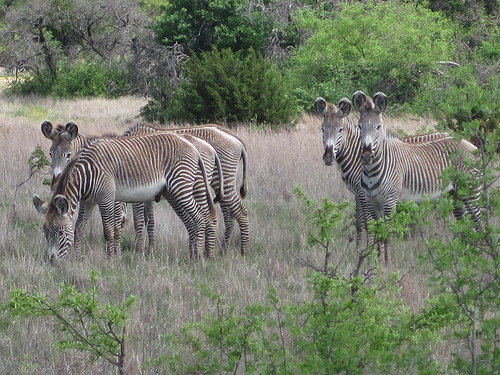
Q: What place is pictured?
A: It is a field.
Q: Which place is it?
A: It is a field.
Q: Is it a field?
A: Yes, it is a field.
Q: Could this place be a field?
A: Yes, it is a field.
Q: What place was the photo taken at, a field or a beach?
A: It was taken at a field.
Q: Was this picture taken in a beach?
A: No, the picture was taken in a field.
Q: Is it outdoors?
A: Yes, it is outdoors.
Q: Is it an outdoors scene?
A: Yes, it is outdoors.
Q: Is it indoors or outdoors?
A: It is outdoors.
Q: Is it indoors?
A: No, it is outdoors.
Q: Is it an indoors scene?
A: No, it is outdoors.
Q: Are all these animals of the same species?
A: Yes, all the animals are zebras.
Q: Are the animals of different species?
A: No, all the animals are zebras.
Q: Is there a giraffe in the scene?
A: No, there are no giraffes.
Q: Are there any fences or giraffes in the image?
A: No, there are no giraffes or fences.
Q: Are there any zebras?
A: Yes, there is a zebra.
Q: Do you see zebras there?
A: Yes, there is a zebra.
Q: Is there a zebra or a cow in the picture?
A: Yes, there is a zebra.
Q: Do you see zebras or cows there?
A: Yes, there is a zebra.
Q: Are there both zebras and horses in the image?
A: No, there is a zebra but no horses.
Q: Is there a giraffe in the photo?
A: No, there are no giraffes.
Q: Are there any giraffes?
A: No, there are no giraffes.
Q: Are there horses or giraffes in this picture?
A: No, there are no giraffes or horses.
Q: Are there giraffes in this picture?
A: No, there are no giraffes.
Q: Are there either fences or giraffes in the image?
A: No, there are no giraffes or fences.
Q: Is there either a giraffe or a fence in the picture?
A: No, there are no giraffes or fences.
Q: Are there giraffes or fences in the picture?
A: No, there are no giraffes or fences.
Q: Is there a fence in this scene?
A: No, there are no fences.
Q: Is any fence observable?
A: No, there are no fences.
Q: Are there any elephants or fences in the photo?
A: No, there are no fences or elephants.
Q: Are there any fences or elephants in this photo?
A: No, there are no fences or elephants.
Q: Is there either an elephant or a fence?
A: No, there are no fences or elephants.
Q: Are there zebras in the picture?
A: Yes, there is a zebra.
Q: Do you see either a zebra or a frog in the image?
A: Yes, there is a zebra.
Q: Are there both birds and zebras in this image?
A: No, there is a zebra but no birds.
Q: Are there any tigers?
A: No, there are no tigers.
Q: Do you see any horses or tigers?
A: No, there are no tigers or horses.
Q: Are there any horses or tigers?
A: No, there are no tigers or horses.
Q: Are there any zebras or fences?
A: Yes, there is a zebra.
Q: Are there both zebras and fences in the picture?
A: No, there is a zebra but no fences.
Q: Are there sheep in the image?
A: No, there are no sheep.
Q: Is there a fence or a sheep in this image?
A: No, there are no sheep or fences.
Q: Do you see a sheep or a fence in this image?
A: No, there are no sheep or fences.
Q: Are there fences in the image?
A: No, there are no fences.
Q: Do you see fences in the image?
A: No, there are no fences.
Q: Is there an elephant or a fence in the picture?
A: No, there are no fences or elephants.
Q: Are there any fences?
A: No, there are no fences.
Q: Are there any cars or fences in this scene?
A: No, there are no fences or cars.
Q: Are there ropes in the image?
A: No, there are no ropes.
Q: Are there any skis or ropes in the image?
A: No, there are no ropes or skis.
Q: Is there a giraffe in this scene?
A: No, there are no giraffes.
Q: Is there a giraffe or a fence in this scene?
A: No, there are no giraffes or fences.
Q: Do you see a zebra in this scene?
A: Yes, there is a zebra.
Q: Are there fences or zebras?
A: Yes, there is a zebra.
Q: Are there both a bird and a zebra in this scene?
A: No, there is a zebra but no birds.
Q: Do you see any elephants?
A: No, there are no elephants.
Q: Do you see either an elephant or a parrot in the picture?
A: No, there are no elephants or parrots.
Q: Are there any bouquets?
A: No, there are no bouquets.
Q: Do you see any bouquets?
A: No, there are no bouquets.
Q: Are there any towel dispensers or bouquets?
A: No, there are no bouquets or towel dispensers.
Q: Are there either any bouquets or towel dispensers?
A: No, there are no bouquets or towel dispensers.